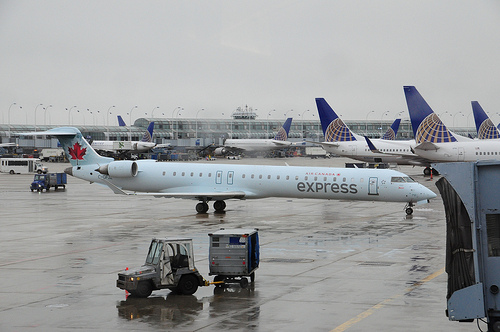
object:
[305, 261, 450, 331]
painted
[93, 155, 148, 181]
engine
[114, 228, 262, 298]
truck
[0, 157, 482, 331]
jetway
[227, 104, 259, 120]
tower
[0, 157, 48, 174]
bus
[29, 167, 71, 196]
truck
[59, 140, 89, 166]
leaf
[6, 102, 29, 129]
lightpost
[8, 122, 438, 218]
airplane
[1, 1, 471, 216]
day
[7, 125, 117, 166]
tail wing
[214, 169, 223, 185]
door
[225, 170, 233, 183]
door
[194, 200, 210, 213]
wheel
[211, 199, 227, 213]
wheel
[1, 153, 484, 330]
tarmac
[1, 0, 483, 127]
sky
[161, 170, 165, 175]
window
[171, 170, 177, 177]
window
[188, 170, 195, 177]
window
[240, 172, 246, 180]
window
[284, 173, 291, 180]
window